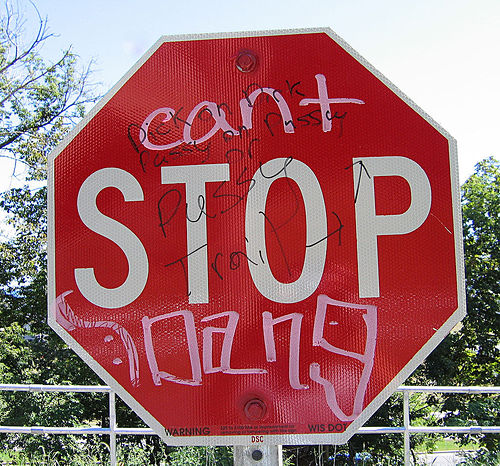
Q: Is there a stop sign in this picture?
A: Yes, there is a stop sign.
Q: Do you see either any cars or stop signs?
A: Yes, there is a stop sign.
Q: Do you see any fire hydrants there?
A: No, there are no fire hydrants.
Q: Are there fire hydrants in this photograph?
A: No, there are no fire hydrants.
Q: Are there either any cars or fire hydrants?
A: No, there are no fire hydrants or cars.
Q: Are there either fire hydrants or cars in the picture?
A: No, there are no fire hydrants or cars.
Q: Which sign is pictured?
A: The sign is a stop sign.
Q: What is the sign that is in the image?
A: The sign is a stop sign.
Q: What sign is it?
A: The sign is a stop sign.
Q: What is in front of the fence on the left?
A: The stop sign is in front of the fence.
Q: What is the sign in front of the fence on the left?
A: The sign is a stop sign.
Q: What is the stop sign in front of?
A: The stop sign is in front of the fence.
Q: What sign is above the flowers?
A: The sign is a stop sign.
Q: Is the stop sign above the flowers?
A: Yes, the stop sign is above the flowers.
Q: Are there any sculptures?
A: No, there are no sculptures.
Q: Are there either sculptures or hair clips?
A: No, there are no sculptures or hair clips.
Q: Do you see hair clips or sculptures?
A: No, there are no sculptures or hair clips.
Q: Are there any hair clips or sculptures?
A: No, there are no sculptures or hair clips.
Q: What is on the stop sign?
A: The graffiti is on the stop sign.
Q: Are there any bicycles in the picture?
A: No, there are no bicycles.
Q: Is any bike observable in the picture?
A: No, there are no bikes.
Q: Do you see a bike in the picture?
A: No, there are no bikes.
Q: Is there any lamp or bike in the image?
A: No, there are no bikes or lamps.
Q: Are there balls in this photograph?
A: No, there are no balls.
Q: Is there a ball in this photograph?
A: No, there are no balls.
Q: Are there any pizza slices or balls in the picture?
A: No, there are no balls or pizza slices.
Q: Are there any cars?
A: No, there are no cars.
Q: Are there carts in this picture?
A: No, there are no carts.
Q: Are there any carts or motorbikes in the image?
A: No, there are no carts or motorbikes.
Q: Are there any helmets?
A: No, there are no helmets.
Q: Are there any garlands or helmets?
A: No, there are no helmets or garlands.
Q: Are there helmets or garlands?
A: No, there are no helmets or garlands.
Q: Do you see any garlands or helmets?
A: No, there are no helmets or garlands.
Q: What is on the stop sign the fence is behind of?
A: The graffiti is on the stop sign.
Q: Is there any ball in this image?
A: No, there are no balls.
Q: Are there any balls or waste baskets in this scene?
A: No, there are no balls or waste baskets.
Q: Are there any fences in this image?
A: Yes, there is a fence.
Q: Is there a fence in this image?
A: Yes, there is a fence.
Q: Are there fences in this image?
A: Yes, there is a fence.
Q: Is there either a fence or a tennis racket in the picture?
A: Yes, there is a fence.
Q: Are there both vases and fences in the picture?
A: No, there is a fence but no vases.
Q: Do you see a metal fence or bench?
A: Yes, there is a metal fence.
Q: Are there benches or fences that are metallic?
A: Yes, the fence is metallic.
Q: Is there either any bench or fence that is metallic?
A: Yes, the fence is metallic.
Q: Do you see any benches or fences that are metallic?
A: Yes, the fence is metallic.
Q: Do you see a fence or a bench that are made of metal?
A: Yes, the fence is made of metal.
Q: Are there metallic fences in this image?
A: Yes, there is a metal fence.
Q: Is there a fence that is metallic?
A: Yes, there is a fence that is metallic.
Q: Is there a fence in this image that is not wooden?
A: Yes, there is a metallic fence.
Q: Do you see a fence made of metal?
A: Yes, there is a fence that is made of metal.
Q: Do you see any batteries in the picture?
A: No, there are no batteries.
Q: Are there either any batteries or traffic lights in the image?
A: No, there are no batteries or traffic lights.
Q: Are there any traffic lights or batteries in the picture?
A: No, there are no batteries or traffic lights.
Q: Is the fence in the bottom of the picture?
A: Yes, the fence is in the bottom of the image.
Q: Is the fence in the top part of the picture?
A: No, the fence is in the bottom of the image.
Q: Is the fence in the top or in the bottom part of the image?
A: The fence is in the bottom of the image.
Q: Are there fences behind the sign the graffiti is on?
A: Yes, there is a fence behind the stop sign.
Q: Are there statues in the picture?
A: No, there are no statues.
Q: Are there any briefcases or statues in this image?
A: No, there are no statues or briefcases.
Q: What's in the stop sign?
A: The graffiti is in the stop sign.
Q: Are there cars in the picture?
A: No, there are no cars.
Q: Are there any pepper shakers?
A: No, there are no pepper shakers.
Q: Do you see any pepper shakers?
A: No, there are no pepper shakers.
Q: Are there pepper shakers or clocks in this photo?
A: No, there are no pepper shakers or clocks.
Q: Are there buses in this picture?
A: No, there are no buses.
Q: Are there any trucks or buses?
A: No, there are no buses or trucks.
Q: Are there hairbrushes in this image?
A: No, there are no hairbrushes.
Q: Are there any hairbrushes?
A: No, there are no hairbrushes.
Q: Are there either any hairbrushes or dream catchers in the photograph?
A: No, there are no hairbrushes or dream catchers.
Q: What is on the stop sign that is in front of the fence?
A: The graffiti is on the stop sign.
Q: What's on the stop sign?
A: The graffiti is on the stop sign.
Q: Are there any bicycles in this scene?
A: No, there are no bicycles.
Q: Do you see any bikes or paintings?
A: No, there are no bikes or paintings.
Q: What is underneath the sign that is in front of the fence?
A: The flowers are underneath the stop sign.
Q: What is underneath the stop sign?
A: The flowers are underneath the stop sign.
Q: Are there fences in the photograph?
A: Yes, there is a fence.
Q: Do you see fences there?
A: Yes, there is a fence.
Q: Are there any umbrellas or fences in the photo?
A: Yes, there is a fence.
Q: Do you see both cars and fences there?
A: No, there is a fence but no cars.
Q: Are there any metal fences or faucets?
A: Yes, there is a metal fence.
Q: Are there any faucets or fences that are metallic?
A: Yes, the fence is metallic.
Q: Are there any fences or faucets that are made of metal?
A: Yes, the fence is made of metal.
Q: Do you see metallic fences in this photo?
A: Yes, there is a metal fence.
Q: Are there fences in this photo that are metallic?
A: Yes, there is a fence that is metallic.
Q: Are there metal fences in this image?
A: Yes, there is a fence that is made of metal.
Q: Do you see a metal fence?
A: Yes, there is a fence that is made of metal.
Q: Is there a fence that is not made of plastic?
A: Yes, there is a fence that is made of metal.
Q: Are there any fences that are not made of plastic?
A: Yes, there is a fence that is made of metal.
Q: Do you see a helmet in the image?
A: No, there are no helmets.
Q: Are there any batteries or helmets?
A: No, there are no helmets or batteries.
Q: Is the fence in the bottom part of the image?
A: Yes, the fence is in the bottom of the image.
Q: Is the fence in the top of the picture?
A: No, the fence is in the bottom of the image.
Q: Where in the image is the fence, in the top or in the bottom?
A: The fence is in the bottom of the image.